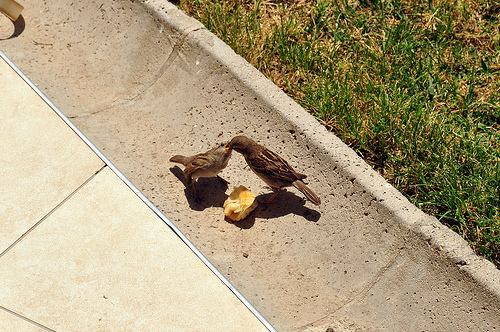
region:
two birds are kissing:
[138, 119, 338, 261]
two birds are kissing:
[155, 136, 311, 227]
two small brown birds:
[163, 121, 319, 228]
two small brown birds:
[144, 94, 334, 279]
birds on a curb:
[165, 122, 322, 241]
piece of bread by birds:
[220, 165, 265, 247]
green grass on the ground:
[333, 10, 449, 123]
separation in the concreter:
[4, 147, 87, 281]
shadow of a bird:
[178, 181, 222, 213]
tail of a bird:
[292, 175, 332, 216]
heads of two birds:
[216, 133, 251, 161]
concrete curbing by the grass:
[337, 123, 469, 295]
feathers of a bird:
[258, 149, 292, 179]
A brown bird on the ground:
[233, 133, 316, 190]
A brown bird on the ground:
[152, 135, 234, 179]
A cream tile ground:
[47, 161, 169, 319]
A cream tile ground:
[12, 277, 164, 330]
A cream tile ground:
[0, 54, 82, 176]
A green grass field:
[420, 70, 496, 217]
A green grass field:
[327, 15, 417, 142]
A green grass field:
[424, 15, 497, 99]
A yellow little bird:
[220, 172, 257, 229]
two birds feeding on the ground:
[165, 126, 322, 190]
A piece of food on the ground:
[224, 186, 256, 221]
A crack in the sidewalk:
[1, 164, 106, 256]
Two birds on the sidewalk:
[171, 135, 321, 209]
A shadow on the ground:
[170, 165, 320, 221]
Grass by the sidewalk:
[172, 0, 498, 267]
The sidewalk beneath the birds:
[2, 0, 499, 330]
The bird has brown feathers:
[230, 133, 317, 203]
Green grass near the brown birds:
[172, 0, 497, 265]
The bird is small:
[168, 140, 226, 195]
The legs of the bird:
[267, 184, 287, 200]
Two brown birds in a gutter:
[168, 132, 323, 223]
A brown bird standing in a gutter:
[233, 132, 323, 209]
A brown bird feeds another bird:
[168, 131, 323, 203]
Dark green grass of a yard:
[352, 14, 487, 136]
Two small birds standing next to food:
[168, 132, 321, 222]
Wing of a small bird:
[249, 153, 305, 183]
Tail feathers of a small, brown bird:
[289, 169, 322, 209]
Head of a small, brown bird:
[228, 134, 256, 155]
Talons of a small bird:
[257, 187, 282, 211]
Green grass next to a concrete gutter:
[357, 127, 497, 266]